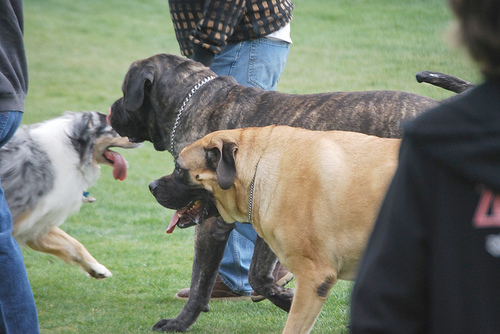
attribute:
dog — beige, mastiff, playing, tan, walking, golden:
[148, 124, 405, 334]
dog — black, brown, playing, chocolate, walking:
[108, 53, 447, 166]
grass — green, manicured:
[21, 0, 197, 334]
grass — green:
[273, 0, 486, 102]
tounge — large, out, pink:
[109, 149, 126, 181]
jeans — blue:
[1, 112, 37, 333]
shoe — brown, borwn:
[208, 276, 246, 302]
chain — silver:
[170, 74, 215, 153]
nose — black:
[149, 180, 160, 195]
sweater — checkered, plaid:
[168, 0, 293, 63]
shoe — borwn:
[272, 261, 292, 286]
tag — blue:
[83, 190, 88, 199]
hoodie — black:
[349, 83, 500, 333]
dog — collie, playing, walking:
[1, 109, 142, 281]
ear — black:
[120, 62, 154, 112]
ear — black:
[206, 141, 238, 190]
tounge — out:
[167, 205, 189, 233]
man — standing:
[166, 0, 293, 86]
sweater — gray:
[1, 0, 29, 114]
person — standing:
[348, 0, 499, 334]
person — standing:
[1, 2, 41, 334]